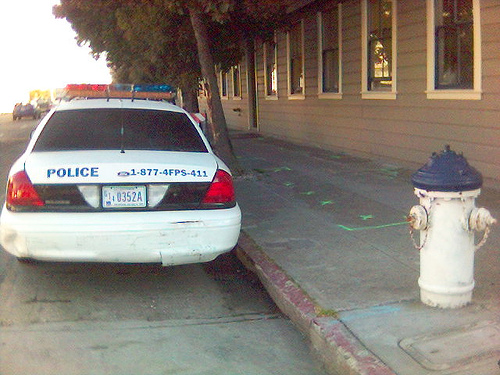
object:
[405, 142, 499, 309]
hydrant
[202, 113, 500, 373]
sidewalk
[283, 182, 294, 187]
marks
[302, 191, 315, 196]
marks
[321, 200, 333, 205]
marks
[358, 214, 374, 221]
marks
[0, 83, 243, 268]
car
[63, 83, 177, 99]
light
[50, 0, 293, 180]
tree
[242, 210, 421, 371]
road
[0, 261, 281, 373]
street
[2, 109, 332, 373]
street